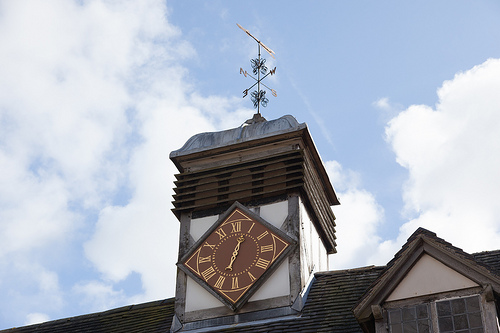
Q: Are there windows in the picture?
A: Yes, there is a window.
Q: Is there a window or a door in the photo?
A: Yes, there is a window.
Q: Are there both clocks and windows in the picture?
A: Yes, there are both a window and a clock.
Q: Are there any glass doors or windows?
A: Yes, there is a glass window.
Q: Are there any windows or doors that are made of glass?
A: Yes, the window is made of glass.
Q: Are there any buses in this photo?
A: No, there are no buses.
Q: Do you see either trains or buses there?
A: No, there are no buses or trains.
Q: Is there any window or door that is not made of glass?
A: No, there is a window but it is made of glass.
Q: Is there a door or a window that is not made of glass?
A: No, there is a window but it is made of glass.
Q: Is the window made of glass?
A: Yes, the window is made of glass.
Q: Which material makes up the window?
A: The window is made of glass.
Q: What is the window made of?
A: The window is made of glass.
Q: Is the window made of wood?
A: No, the window is made of glass.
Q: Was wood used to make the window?
A: No, the window is made of glass.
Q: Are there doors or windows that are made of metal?
A: No, there is a window but it is made of glass.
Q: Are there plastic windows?
A: No, there is a window but it is made of glass.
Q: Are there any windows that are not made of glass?
A: No, there is a window but it is made of glass.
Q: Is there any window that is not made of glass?
A: No, there is a window but it is made of glass.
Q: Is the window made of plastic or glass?
A: The window is made of glass.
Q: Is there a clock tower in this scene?
A: Yes, there is a clock tower.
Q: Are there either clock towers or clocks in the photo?
A: Yes, there is a clock tower.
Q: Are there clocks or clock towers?
A: Yes, there is a clock tower.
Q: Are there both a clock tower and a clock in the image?
A: Yes, there are both a clock tower and a clock.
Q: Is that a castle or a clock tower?
A: That is a clock tower.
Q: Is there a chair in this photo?
A: No, there are no chairs.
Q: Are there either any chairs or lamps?
A: No, there are no chairs or lamps.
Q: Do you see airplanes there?
A: No, there are no airplanes.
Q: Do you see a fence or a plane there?
A: No, there are no airplanes or fences.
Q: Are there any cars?
A: No, there are no cars.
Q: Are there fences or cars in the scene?
A: No, there are no cars or fences.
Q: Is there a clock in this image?
A: Yes, there is a clock.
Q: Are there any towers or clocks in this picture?
A: Yes, there is a clock.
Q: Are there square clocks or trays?
A: Yes, there is a square clock.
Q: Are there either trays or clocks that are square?
A: Yes, the clock is square.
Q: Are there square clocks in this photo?
A: Yes, there is a square clock.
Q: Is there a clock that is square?
A: Yes, there is a clock that is square.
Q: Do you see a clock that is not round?
A: Yes, there is a square clock.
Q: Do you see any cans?
A: No, there are no cans.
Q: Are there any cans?
A: No, there are no cans.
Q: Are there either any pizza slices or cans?
A: No, there are no cans or pizza slices.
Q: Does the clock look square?
A: Yes, the clock is square.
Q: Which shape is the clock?
A: The clock is square.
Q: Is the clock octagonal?
A: No, the clock is square.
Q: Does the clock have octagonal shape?
A: No, the clock is square.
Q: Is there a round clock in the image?
A: No, there is a clock but it is square.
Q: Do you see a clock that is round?
A: No, there is a clock but it is square.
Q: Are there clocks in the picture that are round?
A: No, there is a clock but it is square.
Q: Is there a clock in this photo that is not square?
A: No, there is a clock but it is square.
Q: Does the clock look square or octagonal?
A: The clock is square.